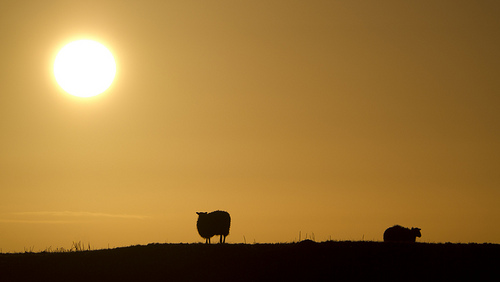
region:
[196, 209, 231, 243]
Sheep enjoying the sunrise.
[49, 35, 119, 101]
The rising sun.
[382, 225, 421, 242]
Sheep resting during the sunrise.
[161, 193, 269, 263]
sheep standing in field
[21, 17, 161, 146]
setting evening sun in sky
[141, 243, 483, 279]
field covered in grass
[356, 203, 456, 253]
sheep laying in field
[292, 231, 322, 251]
small pile of grass in field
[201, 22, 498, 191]
yellow evening sky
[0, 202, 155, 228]
small white cloud in evening sky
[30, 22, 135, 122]
bright yellow setting sun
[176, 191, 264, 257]
silhouette of sheep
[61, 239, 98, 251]
tall blades of grass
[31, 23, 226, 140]
the sun in the sky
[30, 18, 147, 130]
the sun in the sky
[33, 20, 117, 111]
the sun in the sky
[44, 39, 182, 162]
the sun in the sky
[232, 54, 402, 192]
a yellow clear sky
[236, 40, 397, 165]
a yellow clear sky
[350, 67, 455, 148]
a yellow clear sky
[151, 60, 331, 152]
a yellow clear sky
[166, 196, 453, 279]
two sheep in the field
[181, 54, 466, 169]
Sky is orange color.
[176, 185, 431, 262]
Sheeps are standing in grass.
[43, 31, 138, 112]
Sun is cirlce shape.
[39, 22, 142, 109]
Sun is shining in the sky.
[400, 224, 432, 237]
two small ears for sheep.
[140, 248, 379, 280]
ground is black color.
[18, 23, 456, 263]
Sky is clear with no clouds.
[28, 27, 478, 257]
out door picture.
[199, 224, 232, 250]
Sheep has four legs.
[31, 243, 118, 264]
grass are in grund.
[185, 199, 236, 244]
a sheep on a hill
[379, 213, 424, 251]
another sheep on a hill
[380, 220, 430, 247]
this sheep is lying down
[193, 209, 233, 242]
this sheep is standing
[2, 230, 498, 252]
grass blades silhouetted against the sunset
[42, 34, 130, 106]
the sun is bright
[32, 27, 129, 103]
the sun is round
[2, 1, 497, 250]
the sky is yellow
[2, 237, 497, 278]
the ground is black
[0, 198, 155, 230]
two thin clouds